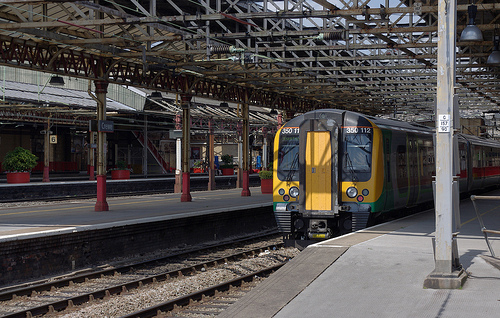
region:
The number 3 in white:
[277, 122, 287, 136]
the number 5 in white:
[283, 125, 290, 135]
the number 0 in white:
[287, 125, 294, 136]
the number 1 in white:
[292, 123, 297, 137]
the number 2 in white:
[366, 124, 372, 134]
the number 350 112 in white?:
[338, 117, 380, 139]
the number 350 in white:
[343, 123, 362, 138]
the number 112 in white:
[357, 122, 373, 135]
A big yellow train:
[248, 86, 498, 248]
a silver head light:
[283, 181, 303, 200]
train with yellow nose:
[169, 77, 411, 293]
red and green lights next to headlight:
[331, 171, 381, 226]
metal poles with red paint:
[5, 62, 299, 214]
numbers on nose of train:
[282, 90, 387, 157]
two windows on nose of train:
[274, 110, 382, 239]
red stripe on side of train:
[385, 119, 498, 216]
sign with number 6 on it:
[13, 111, 73, 182]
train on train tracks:
[153, 108, 393, 310]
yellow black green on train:
[273, 104, 390, 236]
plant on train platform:
[8, 120, 142, 251]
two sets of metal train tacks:
[6, 222, 306, 317]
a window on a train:
[339, 126, 374, 178]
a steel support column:
[81, 71, 127, 216]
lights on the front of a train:
[346, 182, 376, 207]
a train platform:
[216, 233, 389, 315]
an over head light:
[460, 6, 485, 50]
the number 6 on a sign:
[48, 133, 58, 143]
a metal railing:
[465, 181, 497, 273]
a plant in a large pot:
[0, 145, 39, 182]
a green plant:
[256, 167, 275, 178]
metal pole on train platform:
[423, 0, 467, 291]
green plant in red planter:
[3, 145, 41, 182]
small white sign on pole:
[436, 112, 453, 133]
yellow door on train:
[304, 132, 331, 209]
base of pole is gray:
[421, 268, 471, 286]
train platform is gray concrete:
[213, 207, 498, 316]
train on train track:
[0, 240, 313, 312]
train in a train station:
[273, 107, 499, 249]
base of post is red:
[93, 175, 110, 210]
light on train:
[346, 186, 358, 196]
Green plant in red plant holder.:
[7, 142, 62, 204]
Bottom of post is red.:
[72, 166, 154, 253]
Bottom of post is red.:
[178, 167, 225, 253]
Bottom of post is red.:
[232, 159, 262, 226]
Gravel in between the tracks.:
[104, 263, 151, 314]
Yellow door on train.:
[248, 116, 323, 238]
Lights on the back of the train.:
[268, 177, 386, 215]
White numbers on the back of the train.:
[272, 117, 382, 149]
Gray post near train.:
[429, 72, 465, 306]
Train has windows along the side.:
[383, 119, 498, 195]